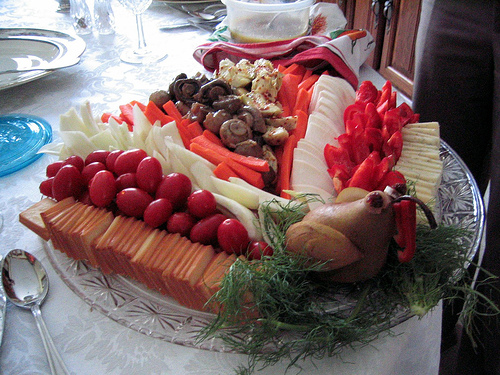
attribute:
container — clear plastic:
[217, 0, 315, 50]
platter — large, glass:
[63, 109, 497, 340]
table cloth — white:
[0, 0, 461, 373]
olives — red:
[35, 142, 275, 261]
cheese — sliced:
[398, 121, 440, 210]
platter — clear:
[35, 102, 485, 353]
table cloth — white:
[77, 327, 143, 373]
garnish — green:
[206, 186, 473, 358]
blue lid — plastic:
[2, 110, 49, 182]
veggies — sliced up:
[191, 42, 400, 190]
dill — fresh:
[196, 326, 334, 374]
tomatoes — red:
[30, 146, 283, 261]